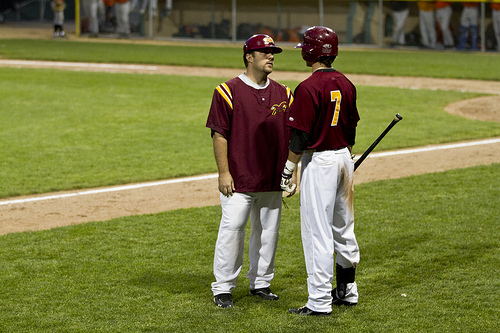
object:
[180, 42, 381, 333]
these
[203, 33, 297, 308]
players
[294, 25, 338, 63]
helmet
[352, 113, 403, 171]
bat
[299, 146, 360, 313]
trousers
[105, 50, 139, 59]
grass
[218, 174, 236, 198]
hand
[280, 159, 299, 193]
glove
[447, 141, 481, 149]
line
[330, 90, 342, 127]
number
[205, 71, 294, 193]
jersey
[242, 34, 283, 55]
cap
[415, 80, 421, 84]
dirt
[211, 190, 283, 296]
pants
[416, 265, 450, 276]
shadow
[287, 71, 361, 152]
shirt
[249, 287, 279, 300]
shoes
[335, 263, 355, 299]
cleats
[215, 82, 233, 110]
stripe